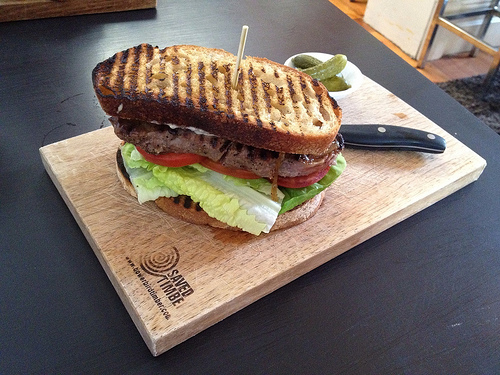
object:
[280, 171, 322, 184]
tomato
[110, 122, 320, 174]
steak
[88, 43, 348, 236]
sandwich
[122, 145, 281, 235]
lettuce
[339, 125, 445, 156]
utensil handle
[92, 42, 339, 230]
board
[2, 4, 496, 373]
table